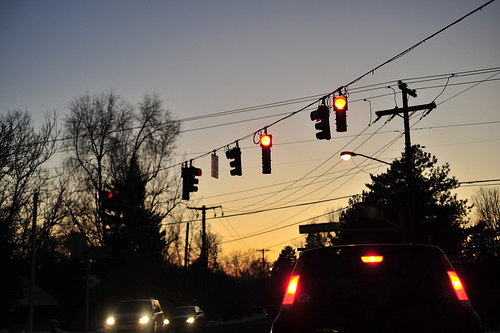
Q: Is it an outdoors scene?
A: Yes, it is outdoors.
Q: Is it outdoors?
A: Yes, it is outdoors.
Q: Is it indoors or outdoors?
A: It is outdoors.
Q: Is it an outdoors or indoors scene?
A: It is outdoors.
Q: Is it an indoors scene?
A: No, it is outdoors.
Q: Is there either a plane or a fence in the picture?
A: No, there are no fences or airplanes.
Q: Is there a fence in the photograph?
A: No, there are no fences.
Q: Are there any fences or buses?
A: No, there are no fences or buses.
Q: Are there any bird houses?
A: No, there are no bird houses.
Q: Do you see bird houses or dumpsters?
A: No, there are no bird houses or dumpsters.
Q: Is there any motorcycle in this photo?
A: Yes, there are motorcycles.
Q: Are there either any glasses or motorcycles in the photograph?
A: Yes, there are motorcycles.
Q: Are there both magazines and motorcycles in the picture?
A: No, there are motorcycles but no magazines.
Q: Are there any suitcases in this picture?
A: No, there are no suitcases.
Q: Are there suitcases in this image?
A: No, there are no suitcases.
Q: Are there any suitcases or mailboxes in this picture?
A: No, there are no suitcases or mailboxes.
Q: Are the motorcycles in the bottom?
A: Yes, the motorcycles are in the bottom of the image.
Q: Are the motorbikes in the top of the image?
A: No, the motorbikes are in the bottom of the image.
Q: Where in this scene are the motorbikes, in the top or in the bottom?
A: The motorbikes are in the bottom of the image.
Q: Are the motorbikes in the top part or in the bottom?
A: The motorbikes are in the bottom of the image.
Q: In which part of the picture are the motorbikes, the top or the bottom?
A: The motorbikes are in the bottom of the image.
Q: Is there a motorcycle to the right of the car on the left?
A: Yes, there are motorcycles to the right of the car.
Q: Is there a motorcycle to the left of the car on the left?
A: No, the motorcycles are to the right of the car.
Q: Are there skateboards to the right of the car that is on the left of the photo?
A: No, there are motorcycles to the right of the car.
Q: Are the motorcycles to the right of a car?
A: Yes, the motorcycles are to the right of a car.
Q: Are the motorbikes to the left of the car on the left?
A: No, the motorbikes are to the right of the car.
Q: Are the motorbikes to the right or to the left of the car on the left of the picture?
A: The motorbikes are to the right of the car.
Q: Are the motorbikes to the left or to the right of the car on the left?
A: The motorbikes are to the right of the car.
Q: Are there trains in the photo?
A: No, there are no trains.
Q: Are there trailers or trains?
A: No, there are no trains or trailers.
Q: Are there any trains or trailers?
A: No, there are no trains or trailers.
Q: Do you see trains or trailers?
A: No, there are no trains or trailers.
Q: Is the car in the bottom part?
A: Yes, the car is in the bottom of the image.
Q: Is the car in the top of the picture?
A: No, the car is in the bottom of the image.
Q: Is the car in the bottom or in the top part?
A: The car is in the bottom of the image.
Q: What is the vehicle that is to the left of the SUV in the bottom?
A: The vehicle is a car.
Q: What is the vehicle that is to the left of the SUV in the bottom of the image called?
A: The vehicle is a car.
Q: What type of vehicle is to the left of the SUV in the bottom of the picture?
A: The vehicle is a car.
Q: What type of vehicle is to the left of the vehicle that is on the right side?
A: The vehicle is a car.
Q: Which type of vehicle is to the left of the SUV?
A: The vehicle is a car.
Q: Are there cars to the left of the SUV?
A: Yes, there is a car to the left of the SUV.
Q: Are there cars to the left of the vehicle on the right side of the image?
A: Yes, there is a car to the left of the SUV.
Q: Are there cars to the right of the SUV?
A: No, the car is to the left of the SUV.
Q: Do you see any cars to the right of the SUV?
A: No, the car is to the left of the SUV.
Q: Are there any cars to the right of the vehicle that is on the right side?
A: No, the car is to the left of the SUV.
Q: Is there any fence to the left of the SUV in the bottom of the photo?
A: No, there is a car to the left of the SUV.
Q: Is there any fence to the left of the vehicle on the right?
A: No, there is a car to the left of the SUV.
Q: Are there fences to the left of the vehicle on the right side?
A: No, there is a car to the left of the SUV.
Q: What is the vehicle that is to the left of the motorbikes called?
A: The vehicle is a car.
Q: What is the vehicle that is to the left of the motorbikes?
A: The vehicle is a car.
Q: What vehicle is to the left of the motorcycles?
A: The vehicle is a car.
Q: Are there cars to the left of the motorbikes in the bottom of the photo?
A: Yes, there is a car to the left of the motorbikes.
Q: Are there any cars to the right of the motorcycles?
A: No, the car is to the left of the motorcycles.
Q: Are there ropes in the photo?
A: No, there are no ropes.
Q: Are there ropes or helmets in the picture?
A: No, there are no ropes or helmets.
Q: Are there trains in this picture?
A: No, there are no trains.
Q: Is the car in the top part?
A: No, the car is in the bottom of the image.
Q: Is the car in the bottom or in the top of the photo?
A: The car is in the bottom of the image.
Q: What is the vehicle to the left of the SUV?
A: The vehicle is a car.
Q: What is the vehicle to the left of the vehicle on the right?
A: The vehicle is a car.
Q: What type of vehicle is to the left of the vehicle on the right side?
A: The vehicle is a car.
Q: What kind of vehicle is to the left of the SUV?
A: The vehicle is a car.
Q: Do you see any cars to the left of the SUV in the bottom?
A: Yes, there is a car to the left of the SUV.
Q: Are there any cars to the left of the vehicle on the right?
A: Yes, there is a car to the left of the SUV.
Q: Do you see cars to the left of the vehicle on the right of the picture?
A: Yes, there is a car to the left of the SUV.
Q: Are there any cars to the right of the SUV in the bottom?
A: No, the car is to the left of the SUV.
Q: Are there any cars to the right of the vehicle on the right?
A: No, the car is to the left of the SUV.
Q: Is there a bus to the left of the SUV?
A: No, there is a car to the left of the SUV.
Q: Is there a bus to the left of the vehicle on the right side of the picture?
A: No, there is a car to the left of the SUV.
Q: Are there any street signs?
A: Yes, there is a street sign.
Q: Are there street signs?
A: Yes, there is a street sign.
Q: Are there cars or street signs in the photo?
A: Yes, there is a street sign.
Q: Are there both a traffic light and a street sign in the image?
A: Yes, there are both a street sign and a traffic light.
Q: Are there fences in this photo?
A: No, there are no fences.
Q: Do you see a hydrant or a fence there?
A: No, there are no fences or fire hydrants.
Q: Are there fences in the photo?
A: No, there are no fences.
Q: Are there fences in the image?
A: No, there are no fences.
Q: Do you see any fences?
A: No, there are no fences.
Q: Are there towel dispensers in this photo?
A: No, there are no towel dispensers.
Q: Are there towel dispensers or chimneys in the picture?
A: No, there are no towel dispensers or chimneys.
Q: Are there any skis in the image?
A: No, there are no skis.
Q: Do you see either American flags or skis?
A: No, there are no skis or American flags.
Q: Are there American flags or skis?
A: No, there are no skis or American flags.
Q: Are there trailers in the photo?
A: No, there are no trailers.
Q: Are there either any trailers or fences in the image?
A: No, there are no trailers or fences.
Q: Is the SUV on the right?
A: Yes, the SUV is on the right of the image.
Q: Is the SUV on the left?
A: No, the SUV is on the right of the image.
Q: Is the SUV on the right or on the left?
A: The SUV is on the right of the image.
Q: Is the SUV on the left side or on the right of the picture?
A: The SUV is on the right of the image.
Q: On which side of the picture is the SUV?
A: The SUV is on the right of the image.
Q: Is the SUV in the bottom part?
A: Yes, the SUV is in the bottom of the image.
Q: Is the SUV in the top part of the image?
A: No, the SUV is in the bottom of the image.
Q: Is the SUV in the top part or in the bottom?
A: The SUV is in the bottom of the image.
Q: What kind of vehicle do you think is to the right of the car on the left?
A: The vehicle is a SUV.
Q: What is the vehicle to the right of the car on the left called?
A: The vehicle is a SUV.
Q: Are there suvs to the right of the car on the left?
A: Yes, there is a SUV to the right of the car.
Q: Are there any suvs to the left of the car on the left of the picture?
A: No, the SUV is to the right of the car.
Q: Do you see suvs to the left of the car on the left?
A: No, the SUV is to the right of the car.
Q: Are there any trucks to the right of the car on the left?
A: No, there is a SUV to the right of the car.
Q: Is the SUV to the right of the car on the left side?
A: Yes, the SUV is to the right of the car.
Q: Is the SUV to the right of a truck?
A: No, the SUV is to the right of the car.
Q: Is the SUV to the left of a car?
A: No, the SUV is to the right of a car.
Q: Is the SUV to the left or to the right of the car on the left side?
A: The SUV is to the right of the car.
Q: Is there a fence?
A: No, there are no fences.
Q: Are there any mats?
A: No, there are no mats.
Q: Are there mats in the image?
A: No, there are no mats.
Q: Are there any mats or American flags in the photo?
A: No, there are no mats or American flags.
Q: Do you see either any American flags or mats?
A: No, there are no mats or American flags.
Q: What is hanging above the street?
A: The traffic lights are hanging above the street.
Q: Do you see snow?
A: Yes, there is snow.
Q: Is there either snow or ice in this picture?
A: Yes, there is snow.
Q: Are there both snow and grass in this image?
A: No, there is snow but no grass.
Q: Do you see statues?
A: No, there are no statues.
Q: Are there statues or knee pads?
A: No, there are no statues or knee pads.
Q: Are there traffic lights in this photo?
A: Yes, there is a traffic light.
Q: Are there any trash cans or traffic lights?
A: Yes, there is a traffic light.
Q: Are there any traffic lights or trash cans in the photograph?
A: Yes, there is a traffic light.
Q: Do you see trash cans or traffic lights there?
A: Yes, there is a traffic light.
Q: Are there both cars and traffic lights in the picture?
A: Yes, there are both a traffic light and a car.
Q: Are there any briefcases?
A: No, there are no briefcases.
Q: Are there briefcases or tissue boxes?
A: No, there are no briefcases or tissue boxes.